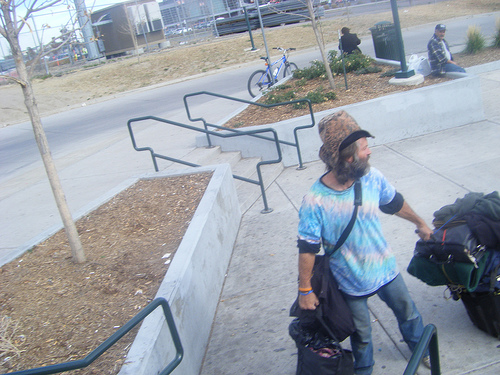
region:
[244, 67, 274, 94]
a wheel of a bicycle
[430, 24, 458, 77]
a sitting on a curb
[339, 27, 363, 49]
a sitting on a curb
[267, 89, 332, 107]
bushes in the dirt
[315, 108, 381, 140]
a hat on a head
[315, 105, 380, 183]
a man with a beard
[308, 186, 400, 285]
a tied dyed t shirt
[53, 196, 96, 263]
a trunk of a tree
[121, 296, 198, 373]
a metal bar hand rail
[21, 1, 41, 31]
a branch of a tree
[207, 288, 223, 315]
edge of a road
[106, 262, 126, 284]
part of a ground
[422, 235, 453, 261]
edge of a bag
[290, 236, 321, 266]
edge of a sleeve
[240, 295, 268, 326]
part of a floor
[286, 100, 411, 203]
the man has a beard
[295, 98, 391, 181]
the man is wearing a strange hat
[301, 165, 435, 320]
the man is wearing a tie dye shirt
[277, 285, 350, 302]
the man is wearing two bracelets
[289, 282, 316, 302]
the bracelets are blue & orange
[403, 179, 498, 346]
the man is dragging loaded suitcase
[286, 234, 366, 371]
the man is carrying two other bags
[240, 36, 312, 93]
the bicycle is blue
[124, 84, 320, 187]
the stair rails are iron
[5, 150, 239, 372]
the planter box is concrete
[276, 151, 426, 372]
A man is visible.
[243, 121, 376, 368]
A man is visible.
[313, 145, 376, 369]
A man is visible.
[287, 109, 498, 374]
man carrying belongings by hands and shoulder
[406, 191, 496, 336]
blankets and luggage strapped together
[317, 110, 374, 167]
tall hat on the man's head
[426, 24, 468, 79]
man sitting on the ground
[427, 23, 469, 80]
man sitting down watching man carry luggage and bags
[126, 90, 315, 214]
two metal hand rails beside the steps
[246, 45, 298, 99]
blue bicycle standing on the sidewalk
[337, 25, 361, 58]
woman sitting on small wall retainer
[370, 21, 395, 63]
trash can on the sidewalk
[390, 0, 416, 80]
bottom of a green pole